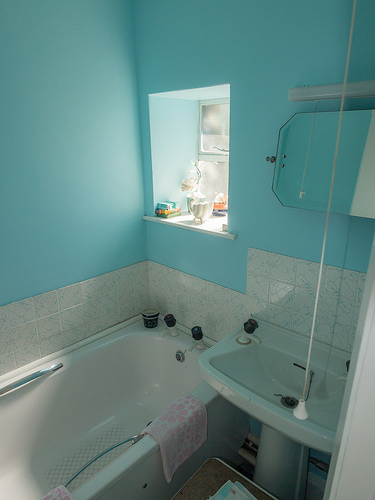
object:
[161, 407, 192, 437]
flowers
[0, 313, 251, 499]
bathtub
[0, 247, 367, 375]
tile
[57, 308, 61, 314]
swirls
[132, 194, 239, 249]
shelving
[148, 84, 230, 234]
window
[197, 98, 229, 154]
mirror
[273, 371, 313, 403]
chain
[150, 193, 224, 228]
shampoos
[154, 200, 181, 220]
toys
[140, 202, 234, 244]
sill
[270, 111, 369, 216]
cabinet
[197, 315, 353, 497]
sink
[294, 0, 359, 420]
cord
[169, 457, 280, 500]
floor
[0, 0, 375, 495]
wall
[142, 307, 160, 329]
cup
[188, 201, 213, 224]
bowl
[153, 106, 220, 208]
hole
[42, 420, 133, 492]
ledge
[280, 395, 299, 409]
drain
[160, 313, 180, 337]
faucet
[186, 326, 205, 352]
faucet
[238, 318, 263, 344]
faucet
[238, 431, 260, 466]
vent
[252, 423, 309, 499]
pedestal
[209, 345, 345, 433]
basin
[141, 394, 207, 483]
towel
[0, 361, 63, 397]
handle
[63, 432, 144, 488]
handle